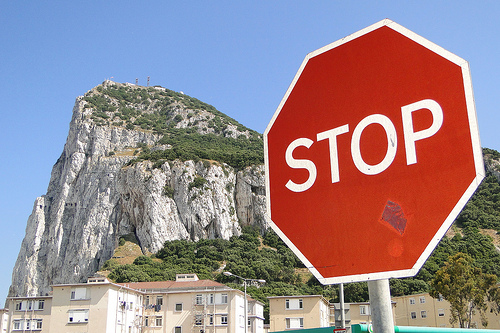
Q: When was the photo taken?
A: Daytime.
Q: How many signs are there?
A: One.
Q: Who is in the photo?
A: Nobody.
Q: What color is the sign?
A: Red.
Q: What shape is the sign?
A: Octagon.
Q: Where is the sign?
A: On a post.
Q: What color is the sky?
A: Blue.